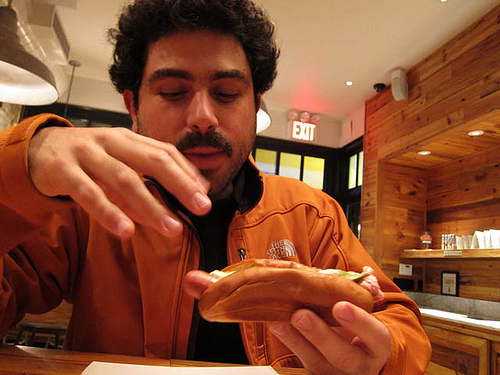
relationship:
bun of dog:
[234, 269, 372, 322] [169, 247, 360, 326]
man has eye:
[0, 20, 312, 298] [201, 51, 259, 106]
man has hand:
[0, 20, 312, 298] [27, 126, 185, 270]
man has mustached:
[0, 20, 312, 298] [169, 121, 251, 146]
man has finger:
[0, 20, 312, 298] [65, 142, 196, 258]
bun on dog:
[234, 269, 372, 322] [169, 247, 360, 326]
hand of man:
[27, 126, 185, 270] [0, 20, 312, 298]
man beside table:
[0, 20, 312, 298] [29, 299, 189, 374]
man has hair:
[0, 20, 312, 298] [228, 13, 269, 42]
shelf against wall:
[397, 204, 499, 275] [404, 129, 493, 208]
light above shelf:
[249, 81, 284, 133] [397, 204, 499, 275]